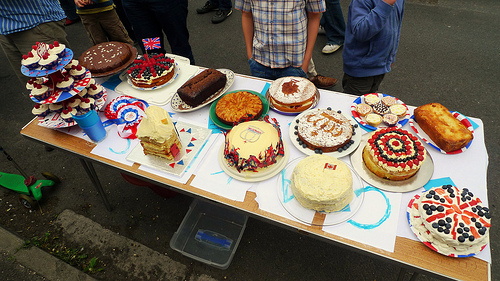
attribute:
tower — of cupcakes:
[17, 33, 107, 135]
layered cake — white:
[121, 86, 196, 167]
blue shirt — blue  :
[344, 27, 399, 75]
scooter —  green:
[0, 150, 50, 210]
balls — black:
[431, 206, 482, 243]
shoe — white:
[322, 39, 338, 55]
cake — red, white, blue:
[278, 150, 372, 220]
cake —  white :
[288, 156, 358, 213]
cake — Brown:
[175, 66, 228, 108]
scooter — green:
[2, 151, 55, 212]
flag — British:
[133, 26, 168, 63]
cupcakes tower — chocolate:
[16, 32, 110, 130]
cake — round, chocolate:
[82, 41, 137, 73]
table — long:
[388, 240, 497, 279]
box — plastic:
[163, 207, 248, 271]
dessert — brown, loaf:
[171, 58, 234, 125]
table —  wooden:
[19, 50, 495, 279]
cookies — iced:
[358, 94, 404, 130]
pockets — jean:
[270, 46, 359, 91]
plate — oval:
[159, 61, 239, 118]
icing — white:
[22, 33, 67, 69]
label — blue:
[194, 226, 233, 249]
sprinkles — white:
[268, 77, 318, 107]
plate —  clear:
[278, 153, 365, 225]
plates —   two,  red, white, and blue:
[348, 91, 410, 131]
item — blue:
[77, 107, 107, 138]